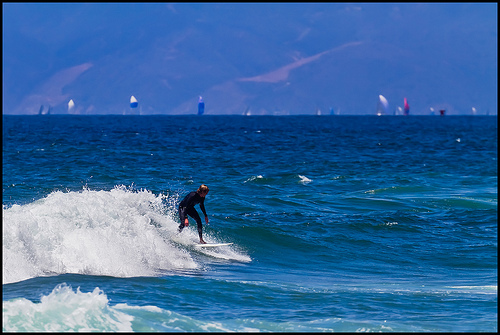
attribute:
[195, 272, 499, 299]
line — white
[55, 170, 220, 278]
wave — white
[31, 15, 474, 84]
sky — blue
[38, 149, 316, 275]
water — white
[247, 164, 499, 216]
curves — green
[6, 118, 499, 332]
water — blue, white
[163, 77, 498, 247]
ocean — blue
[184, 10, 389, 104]
sky — blue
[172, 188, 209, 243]
wet suit — black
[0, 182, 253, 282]
wave — small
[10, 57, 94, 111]
cloud — white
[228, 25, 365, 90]
cloud — white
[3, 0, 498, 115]
sky — blue